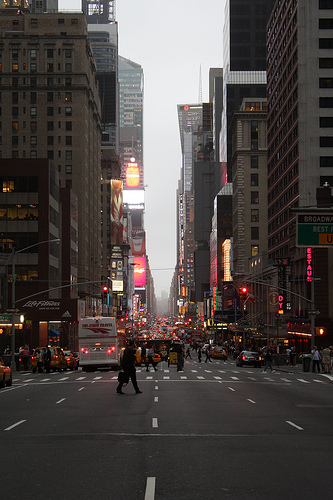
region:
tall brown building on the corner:
[1, 12, 103, 360]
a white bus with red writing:
[76, 315, 119, 372]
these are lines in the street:
[0, 366, 331, 496]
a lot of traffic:
[143, 314, 188, 339]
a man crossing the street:
[114, 338, 143, 396]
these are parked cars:
[175, 309, 266, 369]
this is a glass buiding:
[116, 54, 144, 317]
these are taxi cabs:
[29, 343, 77, 373]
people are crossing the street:
[138, 340, 225, 373]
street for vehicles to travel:
[18, 374, 324, 488]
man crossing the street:
[111, 340, 154, 397]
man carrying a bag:
[116, 368, 130, 387]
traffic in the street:
[150, 320, 174, 344]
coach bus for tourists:
[73, 315, 121, 372]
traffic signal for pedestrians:
[314, 320, 324, 341]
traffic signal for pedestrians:
[14, 313, 27, 327]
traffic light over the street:
[229, 283, 250, 303]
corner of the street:
[292, 350, 321, 381]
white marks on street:
[52, 370, 292, 387]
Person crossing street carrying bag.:
[85, 310, 180, 421]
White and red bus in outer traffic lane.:
[68, 305, 127, 382]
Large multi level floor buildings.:
[1, 7, 155, 369]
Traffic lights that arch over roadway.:
[19, 277, 330, 357]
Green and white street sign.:
[284, 207, 331, 261]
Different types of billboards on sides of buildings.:
[99, 167, 156, 290]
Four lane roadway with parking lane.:
[2, 315, 331, 457]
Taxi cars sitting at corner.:
[22, 333, 85, 408]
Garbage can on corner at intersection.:
[277, 312, 330, 392]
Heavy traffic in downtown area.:
[50, 265, 310, 411]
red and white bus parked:
[64, 306, 121, 373]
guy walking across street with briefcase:
[111, 338, 148, 401]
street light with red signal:
[231, 279, 252, 300]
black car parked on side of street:
[233, 349, 263, 370]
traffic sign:
[286, 199, 330, 256]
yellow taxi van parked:
[31, 341, 67, 368]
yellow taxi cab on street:
[133, 345, 164, 372]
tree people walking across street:
[32, 344, 53, 371]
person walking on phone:
[306, 345, 325, 373]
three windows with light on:
[241, 99, 264, 116]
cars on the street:
[144, 308, 177, 361]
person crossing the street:
[112, 335, 142, 395]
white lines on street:
[211, 369, 294, 395]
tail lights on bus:
[69, 339, 119, 354]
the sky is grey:
[147, 144, 165, 227]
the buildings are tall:
[190, 66, 275, 274]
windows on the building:
[119, 59, 144, 120]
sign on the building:
[300, 242, 322, 286]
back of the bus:
[64, 321, 115, 336]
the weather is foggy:
[163, 139, 175, 189]